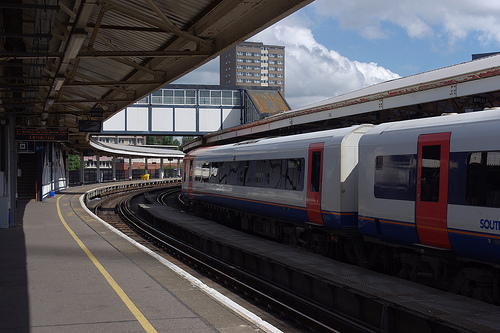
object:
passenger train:
[177, 100, 485, 295]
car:
[176, 119, 378, 254]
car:
[351, 103, 483, 285]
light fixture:
[64, 30, 87, 63]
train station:
[1, 1, 484, 326]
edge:
[102, 219, 158, 257]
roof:
[200, 103, 490, 149]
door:
[184, 133, 453, 235]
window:
[188, 151, 495, 208]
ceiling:
[8, 4, 300, 130]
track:
[92, 186, 498, 332]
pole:
[5, 110, 20, 228]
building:
[231, 41, 290, 85]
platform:
[0, 177, 500, 332]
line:
[70, 178, 291, 333]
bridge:
[114, 81, 292, 131]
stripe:
[309, 142, 323, 224]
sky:
[181, 4, 498, 109]